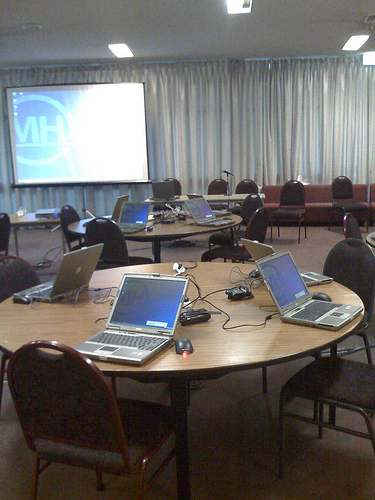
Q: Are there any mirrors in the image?
A: No, there are no mirrors.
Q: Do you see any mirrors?
A: No, there are no mirrors.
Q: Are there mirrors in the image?
A: No, there are no mirrors.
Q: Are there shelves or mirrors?
A: No, there are no mirrors or shelves.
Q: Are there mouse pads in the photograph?
A: No, there are no mouse pads.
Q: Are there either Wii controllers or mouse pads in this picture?
A: No, there are no mouse pads or Wii controllers.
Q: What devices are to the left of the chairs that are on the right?
A: The devices are computers.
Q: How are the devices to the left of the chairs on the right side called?
A: The devices are computers.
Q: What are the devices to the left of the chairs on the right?
A: The devices are computers.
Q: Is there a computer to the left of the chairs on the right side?
A: Yes, there are computers to the left of the chairs.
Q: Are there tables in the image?
A: Yes, there is a table.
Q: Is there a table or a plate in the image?
A: Yes, there is a table.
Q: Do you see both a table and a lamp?
A: No, there is a table but no lamps.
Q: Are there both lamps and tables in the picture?
A: No, there is a table but no lamps.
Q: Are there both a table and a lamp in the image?
A: No, there is a table but no lamps.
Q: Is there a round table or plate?
A: Yes, there is a round table.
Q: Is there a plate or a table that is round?
A: Yes, the table is round.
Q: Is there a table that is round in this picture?
A: Yes, there is a round table.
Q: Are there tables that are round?
A: Yes, there is a table that is round.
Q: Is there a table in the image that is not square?
A: Yes, there is a round table.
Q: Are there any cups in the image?
A: No, there are no cups.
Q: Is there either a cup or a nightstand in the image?
A: No, there are no cups or nightstands.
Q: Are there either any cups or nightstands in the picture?
A: No, there are no cups or nightstands.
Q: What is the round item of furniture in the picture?
A: The piece of furniture is a table.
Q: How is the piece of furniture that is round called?
A: The piece of furniture is a table.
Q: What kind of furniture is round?
A: The furniture is a table.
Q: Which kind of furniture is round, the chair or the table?
A: The table is round.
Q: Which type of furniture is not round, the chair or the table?
A: The chair is not round.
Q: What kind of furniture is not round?
A: The furniture is a chair.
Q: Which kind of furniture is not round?
A: The furniture is a chair.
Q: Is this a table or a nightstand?
A: This is a table.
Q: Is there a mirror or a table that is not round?
A: No, there is a table but it is round.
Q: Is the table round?
A: Yes, the table is round.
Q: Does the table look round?
A: Yes, the table is round.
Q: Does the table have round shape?
A: Yes, the table is round.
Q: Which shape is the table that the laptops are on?
A: The table is round.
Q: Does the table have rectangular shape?
A: No, the table is round.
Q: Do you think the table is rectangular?
A: No, the table is round.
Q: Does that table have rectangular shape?
A: No, the table is round.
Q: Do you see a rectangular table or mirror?
A: No, there is a table but it is round.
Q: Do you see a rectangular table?
A: No, there is a table but it is round.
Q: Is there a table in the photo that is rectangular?
A: No, there is a table but it is round.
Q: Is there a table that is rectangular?
A: No, there is a table but it is round.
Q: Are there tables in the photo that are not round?
A: No, there is a table but it is round.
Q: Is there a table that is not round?
A: No, there is a table but it is round.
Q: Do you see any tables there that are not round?
A: No, there is a table but it is round.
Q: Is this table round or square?
A: The table is round.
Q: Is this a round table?
A: Yes, this is a round table.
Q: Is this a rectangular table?
A: No, this is a round table.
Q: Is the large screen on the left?
A: Yes, the screen is on the left of the image.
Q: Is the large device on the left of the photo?
A: Yes, the screen is on the left of the image.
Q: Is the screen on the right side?
A: No, the screen is on the left of the image.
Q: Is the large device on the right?
A: No, the screen is on the left of the image.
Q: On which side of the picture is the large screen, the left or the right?
A: The screen is on the left of the image.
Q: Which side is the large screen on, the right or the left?
A: The screen is on the left of the image.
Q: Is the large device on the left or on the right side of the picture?
A: The screen is on the left of the image.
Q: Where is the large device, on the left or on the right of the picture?
A: The screen is on the left of the image.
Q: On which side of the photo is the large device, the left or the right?
A: The screen is on the left of the image.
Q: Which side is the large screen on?
A: The screen is on the left of the image.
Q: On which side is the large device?
A: The screen is on the left of the image.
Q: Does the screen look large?
A: Yes, the screen is large.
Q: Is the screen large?
A: Yes, the screen is large.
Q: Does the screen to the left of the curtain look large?
A: Yes, the screen is large.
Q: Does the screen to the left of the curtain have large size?
A: Yes, the screen is large.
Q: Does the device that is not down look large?
A: Yes, the screen is large.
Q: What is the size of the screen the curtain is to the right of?
A: The screen is large.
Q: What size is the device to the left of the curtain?
A: The screen is large.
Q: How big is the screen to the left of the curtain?
A: The screen is large.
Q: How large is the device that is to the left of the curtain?
A: The screen is large.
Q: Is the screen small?
A: No, the screen is large.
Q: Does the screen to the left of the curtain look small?
A: No, the screen is large.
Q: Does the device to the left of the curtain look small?
A: No, the screen is large.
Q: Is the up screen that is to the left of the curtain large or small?
A: The screen is large.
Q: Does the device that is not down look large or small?
A: The screen is large.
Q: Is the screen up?
A: Yes, the screen is up.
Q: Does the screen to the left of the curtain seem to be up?
A: Yes, the screen is up.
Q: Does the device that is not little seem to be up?
A: Yes, the screen is up.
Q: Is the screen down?
A: No, the screen is up.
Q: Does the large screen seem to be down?
A: No, the screen is up.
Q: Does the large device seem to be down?
A: No, the screen is up.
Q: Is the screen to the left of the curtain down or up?
A: The screen is up.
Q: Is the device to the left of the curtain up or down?
A: The screen is up.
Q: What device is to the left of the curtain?
A: The device is a screen.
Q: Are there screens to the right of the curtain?
A: No, the screen is to the left of the curtain.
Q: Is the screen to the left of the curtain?
A: Yes, the screen is to the left of the curtain.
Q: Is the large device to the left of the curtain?
A: Yes, the screen is to the left of the curtain.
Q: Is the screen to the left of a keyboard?
A: No, the screen is to the left of the curtain.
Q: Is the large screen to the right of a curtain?
A: No, the screen is to the left of a curtain.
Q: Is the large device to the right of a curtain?
A: No, the screen is to the left of a curtain.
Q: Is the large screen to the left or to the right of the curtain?
A: The screen is to the left of the curtain.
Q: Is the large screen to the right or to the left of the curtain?
A: The screen is to the left of the curtain.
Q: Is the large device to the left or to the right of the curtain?
A: The screen is to the left of the curtain.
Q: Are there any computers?
A: Yes, there is a computer.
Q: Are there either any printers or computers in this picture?
A: Yes, there is a computer.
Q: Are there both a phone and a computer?
A: No, there is a computer but no phones.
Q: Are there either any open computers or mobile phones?
A: Yes, there is an open computer.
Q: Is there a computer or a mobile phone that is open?
A: Yes, the computer is open.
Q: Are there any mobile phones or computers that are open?
A: Yes, the computer is open.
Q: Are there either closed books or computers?
A: Yes, there is a closed computer.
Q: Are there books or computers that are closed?
A: Yes, the computer is closed.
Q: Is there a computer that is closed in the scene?
A: Yes, there is a closed computer.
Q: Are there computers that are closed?
A: Yes, there is a computer that is closed.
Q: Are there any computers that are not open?
A: Yes, there is an closed computer.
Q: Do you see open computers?
A: Yes, there is an open computer.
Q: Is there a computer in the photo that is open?
A: Yes, there is a computer that is open.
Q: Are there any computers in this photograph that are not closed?
A: Yes, there is a open computer.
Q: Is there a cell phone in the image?
A: No, there are no cell phones.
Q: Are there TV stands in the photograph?
A: No, there are no TV stands.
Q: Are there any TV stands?
A: No, there are no TV stands.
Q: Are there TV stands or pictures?
A: No, there are no TV stands or pictures.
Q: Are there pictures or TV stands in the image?
A: No, there are no TV stands or pictures.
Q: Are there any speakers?
A: No, there are no speakers.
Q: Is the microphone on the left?
A: Yes, the microphone is on the left of the image.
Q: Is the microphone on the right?
A: No, the microphone is on the left of the image.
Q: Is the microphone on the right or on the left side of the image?
A: The microphone is on the left of the image.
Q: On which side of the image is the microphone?
A: The microphone is on the left of the image.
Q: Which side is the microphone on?
A: The microphone is on the left of the image.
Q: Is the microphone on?
A: Yes, the microphone is on.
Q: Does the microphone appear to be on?
A: Yes, the microphone is on.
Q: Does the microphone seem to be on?
A: Yes, the microphone is on.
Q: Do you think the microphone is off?
A: No, the microphone is on.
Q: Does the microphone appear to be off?
A: No, the microphone is on.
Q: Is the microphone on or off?
A: The microphone is on.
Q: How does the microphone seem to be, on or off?
A: The microphone is on.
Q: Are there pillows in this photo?
A: No, there are no pillows.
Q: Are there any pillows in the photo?
A: No, there are no pillows.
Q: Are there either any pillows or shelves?
A: No, there are no pillows or shelves.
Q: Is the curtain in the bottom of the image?
A: No, the curtain is in the top of the image.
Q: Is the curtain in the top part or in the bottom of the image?
A: The curtain is in the top of the image.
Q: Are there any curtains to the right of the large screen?
A: Yes, there is a curtain to the right of the screen.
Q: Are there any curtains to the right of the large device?
A: Yes, there is a curtain to the right of the screen.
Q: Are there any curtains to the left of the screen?
A: No, the curtain is to the right of the screen.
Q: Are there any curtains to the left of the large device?
A: No, the curtain is to the right of the screen.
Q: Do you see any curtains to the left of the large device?
A: No, the curtain is to the right of the screen.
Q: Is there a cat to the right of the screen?
A: No, there is a curtain to the right of the screen.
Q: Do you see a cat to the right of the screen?
A: No, there is a curtain to the right of the screen.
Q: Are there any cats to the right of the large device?
A: No, there is a curtain to the right of the screen.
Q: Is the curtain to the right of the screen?
A: Yes, the curtain is to the right of the screen.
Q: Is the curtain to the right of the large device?
A: Yes, the curtain is to the right of the screen.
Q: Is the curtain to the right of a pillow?
A: No, the curtain is to the right of the screen.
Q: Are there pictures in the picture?
A: No, there are no pictures.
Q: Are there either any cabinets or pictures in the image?
A: No, there are no pictures or cabinets.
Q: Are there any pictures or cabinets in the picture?
A: No, there are no pictures or cabinets.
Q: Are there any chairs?
A: Yes, there is a chair.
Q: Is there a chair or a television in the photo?
A: Yes, there is a chair.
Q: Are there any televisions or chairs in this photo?
A: Yes, there is a chair.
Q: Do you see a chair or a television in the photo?
A: Yes, there is a chair.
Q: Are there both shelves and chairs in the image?
A: No, there is a chair but no shelves.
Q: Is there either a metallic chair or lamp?
A: Yes, there is a metal chair.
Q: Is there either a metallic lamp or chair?
A: Yes, there is a metal chair.